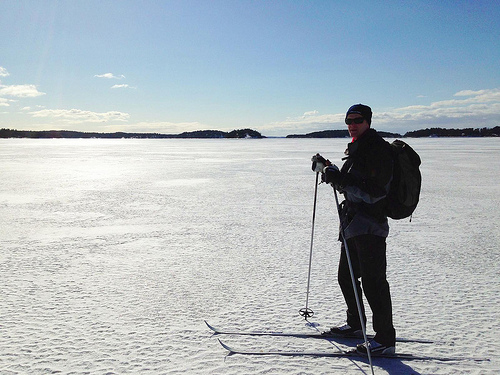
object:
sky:
[67, 27, 426, 113]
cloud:
[95, 72, 125, 82]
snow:
[124, 138, 217, 192]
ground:
[53, 132, 248, 327]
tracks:
[211, 276, 280, 326]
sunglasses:
[345, 116, 367, 124]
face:
[348, 114, 366, 138]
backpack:
[386, 139, 421, 220]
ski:
[202, 320, 435, 344]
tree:
[215, 130, 218, 138]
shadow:
[321, 332, 420, 375]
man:
[309, 104, 398, 358]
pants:
[337, 236, 398, 346]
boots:
[343, 336, 396, 356]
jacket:
[338, 128, 393, 242]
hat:
[346, 104, 372, 119]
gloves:
[311, 156, 332, 173]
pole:
[298, 153, 322, 321]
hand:
[311, 157, 328, 174]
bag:
[385, 139, 421, 220]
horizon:
[1, 119, 482, 152]